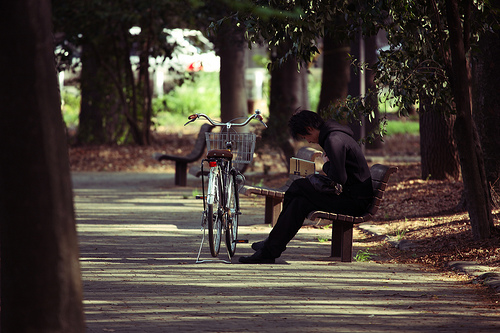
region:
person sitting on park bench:
[239, 105, 372, 262]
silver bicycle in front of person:
[184, 109, 269, 266]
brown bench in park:
[154, 122, 217, 184]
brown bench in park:
[237, 145, 321, 226]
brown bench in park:
[305, 160, 395, 260]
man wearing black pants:
[238, 106, 373, 263]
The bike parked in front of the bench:
[185, 108, 268, 263]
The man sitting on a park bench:
[236, 103, 377, 263]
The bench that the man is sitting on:
[303, 159, 399, 264]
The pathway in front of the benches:
[67, 168, 498, 331]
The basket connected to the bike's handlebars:
[202, 125, 262, 170]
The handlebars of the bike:
[181, 110, 276, 132]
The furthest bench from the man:
[152, 118, 214, 188]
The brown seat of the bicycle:
[205, 144, 237, 163]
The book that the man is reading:
[288, 154, 323, 180]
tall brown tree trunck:
[2, 3, 87, 329]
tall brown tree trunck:
[443, 3, 490, 240]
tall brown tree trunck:
[416, 95, 456, 177]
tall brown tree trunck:
[316, 4, 349, 124]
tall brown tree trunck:
[363, 23, 385, 144]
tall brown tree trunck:
[267, 42, 295, 146]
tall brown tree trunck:
[216, 28, 251, 156]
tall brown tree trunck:
[74, 20, 142, 150]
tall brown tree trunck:
[134, 26, 154, 132]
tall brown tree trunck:
[83, 40, 143, 139]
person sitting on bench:
[46, 57, 441, 332]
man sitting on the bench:
[255, 93, 402, 262]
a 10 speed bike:
[148, 80, 279, 268]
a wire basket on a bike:
[186, 68, 278, 185]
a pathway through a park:
[76, 131, 476, 323]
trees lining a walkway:
[388, 18, 496, 289]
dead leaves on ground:
[395, 155, 481, 269]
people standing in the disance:
[159, 40, 219, 85]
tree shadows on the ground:
[97, 163, 282, 321]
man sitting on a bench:
[238, 111, 373, 263]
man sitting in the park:
[238, 107, 371, 266]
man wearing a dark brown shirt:
[238, 111, 372, 263]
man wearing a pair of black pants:
[240, 108, 371, 265]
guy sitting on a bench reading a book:
[237, 109, 372, 266]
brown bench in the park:
[240, 145, 397, 262]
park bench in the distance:
[155, 122, 211, 183]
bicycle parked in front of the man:
[178, 111, 268, 263]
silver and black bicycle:
[181, 110, 266, 265]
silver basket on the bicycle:
[204, 132, 254, 162]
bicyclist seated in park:
[21, 20, 488, 320]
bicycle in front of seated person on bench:
[171, 106, 383, 266]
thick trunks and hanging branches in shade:
[1, 4, 491, 314]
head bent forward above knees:
[240, 104, 376, 269]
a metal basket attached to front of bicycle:
[205, 120, 255, 174]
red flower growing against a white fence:
[178, 56, 205, 85]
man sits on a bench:
[241, 103, 401, 270]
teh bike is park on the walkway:
[171, 89, 270, 272]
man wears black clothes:
[238, 98, 379, 273]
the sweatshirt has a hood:
[313, 99, 383, 202]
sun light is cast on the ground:
[98, 202, 188, 300]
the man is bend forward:
[246, 101, 378, 270]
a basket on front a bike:
[178, 104, 270, 170]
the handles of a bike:
[176, 103, 276, 138]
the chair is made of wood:
[242, 147, 399, 262]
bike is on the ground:
[176, 101, 267, 272]